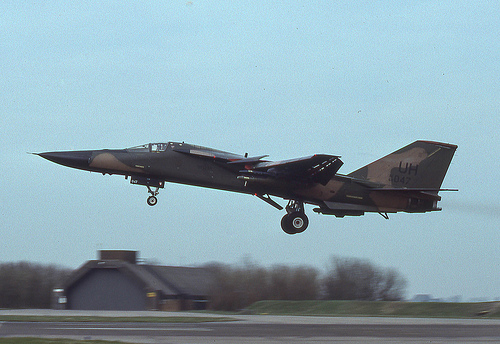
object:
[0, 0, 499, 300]
sky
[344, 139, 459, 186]
tail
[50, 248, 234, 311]
house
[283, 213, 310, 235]
back wheel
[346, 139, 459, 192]
empennage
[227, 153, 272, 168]
wing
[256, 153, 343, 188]
wing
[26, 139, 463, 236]
jet plane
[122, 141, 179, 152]
pilothouse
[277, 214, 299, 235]
wheel